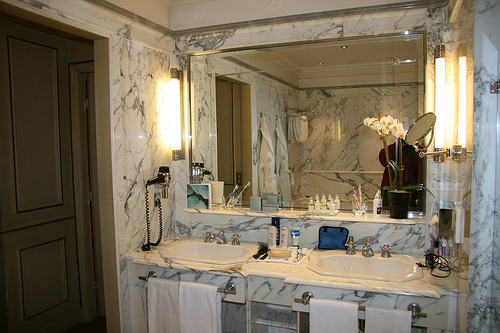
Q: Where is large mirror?
A: Above sink.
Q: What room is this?
A: Bathroom.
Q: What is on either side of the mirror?
A: Lights.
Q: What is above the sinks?
A: A mirror.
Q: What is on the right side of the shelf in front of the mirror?
A: A flowering plant.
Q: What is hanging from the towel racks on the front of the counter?
A: White towels.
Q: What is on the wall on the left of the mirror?
A: A hairdryer.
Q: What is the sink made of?
A: Marble.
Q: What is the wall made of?
A: Marble.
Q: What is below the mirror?
A: Two sinks.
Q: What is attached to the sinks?
A: Faucets.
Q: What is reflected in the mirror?
A: A shower.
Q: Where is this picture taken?
A: In a bathroom.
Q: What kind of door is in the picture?
A: A brown wood door.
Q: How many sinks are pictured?
A: Two.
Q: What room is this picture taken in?
A: Bathroom.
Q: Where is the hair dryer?
A: Left Wall.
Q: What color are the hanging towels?
A: White.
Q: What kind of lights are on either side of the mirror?
A: Fluorescent.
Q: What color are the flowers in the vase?
A: White.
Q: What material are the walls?
A: Marble.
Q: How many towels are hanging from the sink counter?
A: Four.